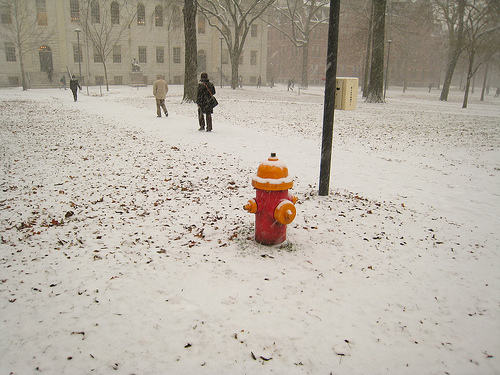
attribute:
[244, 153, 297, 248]
hydrant — red, yellow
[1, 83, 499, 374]
snow — moving, white, grounded, fresh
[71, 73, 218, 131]
people — walking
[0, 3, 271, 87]
building — bricked, large, standing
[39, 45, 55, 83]
door — arched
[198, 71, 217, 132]
man — standing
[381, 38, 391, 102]
pole — light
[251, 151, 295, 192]
top — orange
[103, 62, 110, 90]
trunk — thin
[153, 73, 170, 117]
man — walking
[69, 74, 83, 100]
man — walking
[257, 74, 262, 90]
man — walking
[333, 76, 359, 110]
can — white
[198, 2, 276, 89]
tree — leafless, standing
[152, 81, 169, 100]
jacket — beige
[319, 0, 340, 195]
pole — large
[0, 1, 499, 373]
outside — snowing